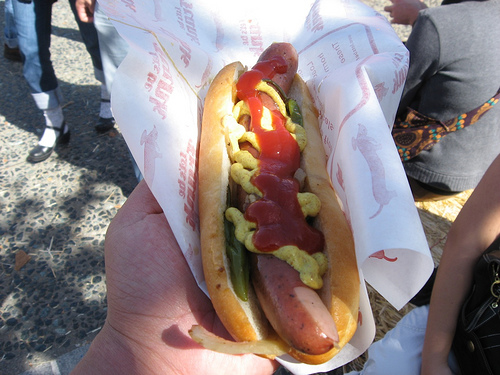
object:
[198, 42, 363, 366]
bun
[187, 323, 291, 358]
onion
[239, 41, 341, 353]
hot dog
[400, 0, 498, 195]
sweater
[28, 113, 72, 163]
shoe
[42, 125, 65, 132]
strap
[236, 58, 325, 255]
ketchup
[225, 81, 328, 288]
mustard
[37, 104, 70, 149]
sock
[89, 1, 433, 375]
paper